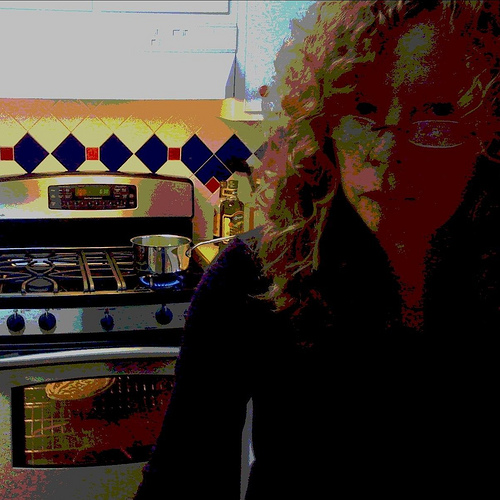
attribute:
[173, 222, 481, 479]
top — black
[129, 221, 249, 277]
pan — silver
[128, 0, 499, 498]
woman — blonde